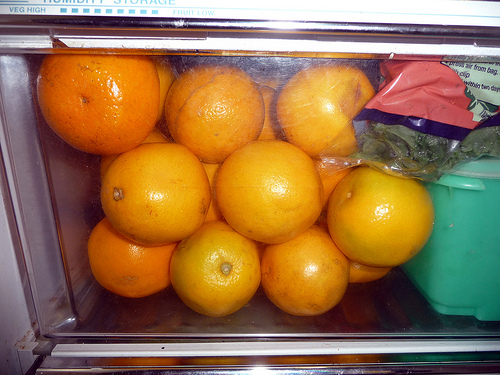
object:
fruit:
[38, 53, 156, 149]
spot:
[75, 88, 95, 112]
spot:
[71, 90, 97, 110]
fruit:
[34, 51, 163, 154]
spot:
[77, 99, 94, 111]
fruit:
[94, 148, 209, 241]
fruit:
[82, 219, 170, 297]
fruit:
[169, 219, 259, 320]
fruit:
[263, 240, 348, 316]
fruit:
[218, 135, 320, 238]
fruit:
[325, 162, 433, 272]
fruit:
[279, 60, 369, 160]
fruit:
[348, 256, 390, 284]